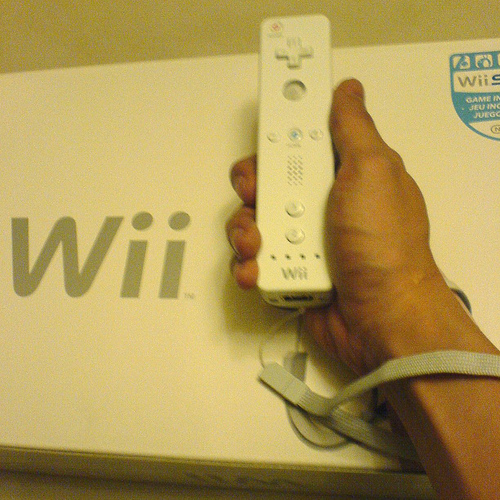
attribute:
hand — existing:
[224, 76, 499, 499]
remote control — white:
[253, 12, 354, 310]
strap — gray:
[254, 306, 499, 470]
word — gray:
[4, 204, 200, 309]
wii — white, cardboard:
[0, 31, 499, 497]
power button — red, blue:
[265, 17, 286, 36]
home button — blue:
[287, 126, 303, 144]